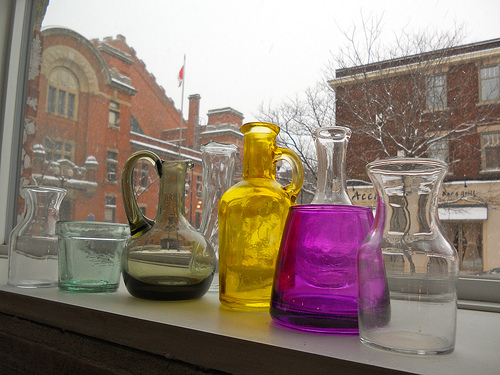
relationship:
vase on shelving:
[355, 156, 461, 355] [3, 253, 500, 375]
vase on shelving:
[278, 204, 389, 317] [3, 253, 500, 375]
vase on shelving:
[218, 119, 287, 309] [3, 253, 500, 375]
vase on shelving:
[117, 149, 216, 299] [3, 253, 500, 375]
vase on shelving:
[9, 182, 67, 286] [3, 253, 500, 375]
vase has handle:
[218, 119, 287, 309] [276, 144, 306, 194]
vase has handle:
[117, 149, 216, 299] [121, 150, 165, 230]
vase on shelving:
[58, 217, 129, 293] [3, 253, 500, 375]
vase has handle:
[117, 149, 216, 299] [276, 144, 306, 194]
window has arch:
[46, 65, 81, 122] [40, 45, 98, 92]